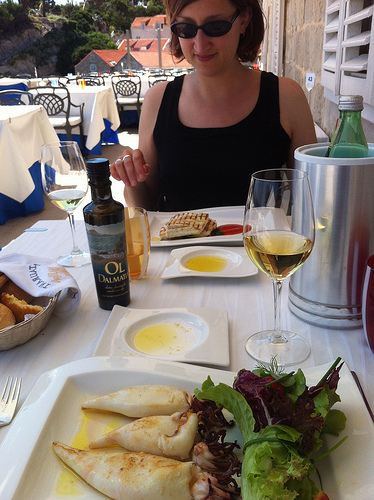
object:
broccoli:
[210, 228, 226, 236]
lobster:
[49, 442, 241, 499]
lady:
[109, 1, 320, 213]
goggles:
[169, 7, 241, 38]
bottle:
[326, 95, 370, 157]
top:
[338, 94, 365, 113]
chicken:
[80, 384, 195, 417]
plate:
[1, 355, 374, 499]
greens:
[233, 431, 318, 499]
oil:
[136, 324, 177, 353]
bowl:
[92, 302, 230, 366]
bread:
[1, 274, 44, 321]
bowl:
[0, 286, 61, 352]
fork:
[0, 376, 21, 426]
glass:
[243, 168, 316, 366]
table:
[0, 219, 373, 500]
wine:
[244, 230, 313, 284]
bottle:
[80, 158, 131, 311]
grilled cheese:
[160, 210, 217, 237]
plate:
[145, 204, 248, 249]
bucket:
[286, 140, 374, 331]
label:
[90, 251, 128, 284]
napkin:
[1, 250, 80, 299]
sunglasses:
[169, 5, 242, 37]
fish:
[160, 210, 212, 236]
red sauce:
[219, 222, 251, 235]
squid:
[185, 433, 234, 475]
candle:
[78, 79, 88, 89]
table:
[18, 88, 121, 154]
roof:
[127, 43, 179, 65]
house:
[74, 32, 145, 73]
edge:
[150, 232, 245, 253]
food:
[158, 211, 210, 234]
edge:
[158, 223, 212, 237]